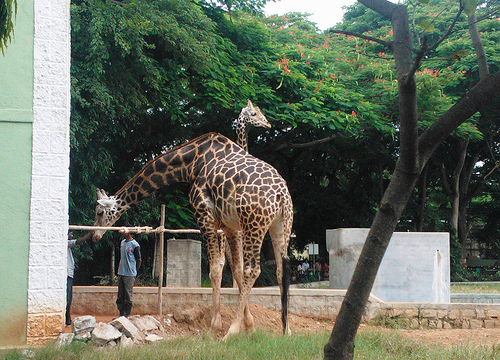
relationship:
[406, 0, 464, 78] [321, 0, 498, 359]
branches on tree trees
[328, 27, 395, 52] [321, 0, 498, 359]
branches on tree trees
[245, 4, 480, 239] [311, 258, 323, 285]
people under tree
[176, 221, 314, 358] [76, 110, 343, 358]
legs of giraffe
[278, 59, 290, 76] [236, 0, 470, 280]
flower in tree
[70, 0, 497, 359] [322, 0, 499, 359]
trees with branches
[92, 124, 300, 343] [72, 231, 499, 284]
giraffe in fence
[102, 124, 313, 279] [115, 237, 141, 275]
giraffe wears blue shirt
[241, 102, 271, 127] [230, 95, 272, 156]
head of giraffe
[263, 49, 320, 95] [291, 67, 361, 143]
flowers on tree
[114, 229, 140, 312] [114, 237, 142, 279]
boy wears blue shirt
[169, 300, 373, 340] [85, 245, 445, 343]
dirt against fence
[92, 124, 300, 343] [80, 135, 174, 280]
giraffe with neck